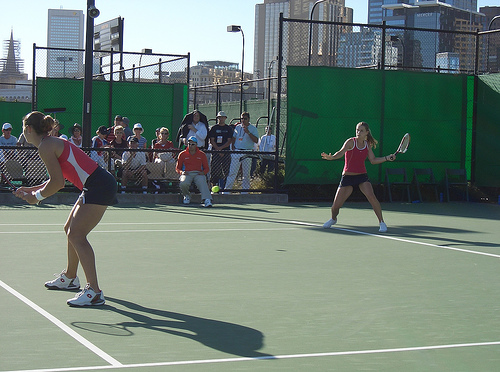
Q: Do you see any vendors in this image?
A: No, there are no vendors.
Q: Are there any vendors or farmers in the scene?
A: No, there are no vendors or farmers.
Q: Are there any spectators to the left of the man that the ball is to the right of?
A: Yes, there is a spectator to the left of the man.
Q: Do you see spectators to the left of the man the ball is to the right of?
A: Yes, there is a spectator to the left of the man.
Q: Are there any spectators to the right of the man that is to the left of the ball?
A: No, the spectator is to the left of the man.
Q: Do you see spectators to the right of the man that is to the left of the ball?
A: No, the spectator is to the left of the man.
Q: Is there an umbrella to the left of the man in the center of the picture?
A: No, there is a spectator to the left of the man.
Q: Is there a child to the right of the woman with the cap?
A: No, there is a spectator to the right of the woman.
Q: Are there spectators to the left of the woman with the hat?
A: Yes, there is a spectator to the left of the woman.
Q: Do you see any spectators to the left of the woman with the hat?
A: Yes, there is a spectator to the left of the woman.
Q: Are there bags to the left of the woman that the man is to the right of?
A: No, there is a spectator to the left of the woman.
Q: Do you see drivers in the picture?
A: No, there are no drivers.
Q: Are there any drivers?
A: No, there are no drivers.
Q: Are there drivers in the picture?
A: No, there are no drivers.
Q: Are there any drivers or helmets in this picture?
A: No, there are no drivers or helmets.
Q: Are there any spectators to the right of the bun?
A: Yes, there is a spectator to the right of the bun.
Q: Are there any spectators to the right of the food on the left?
A: Yes, there is a spectator to the right of the bun.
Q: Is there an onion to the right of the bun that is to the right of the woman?
A: No, there is a spectator to the right of the bun.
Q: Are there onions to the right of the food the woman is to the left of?
A: No, there is a spectator to the right of the bun.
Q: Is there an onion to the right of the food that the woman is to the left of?
A: No, there is a spectator to the right of the bun.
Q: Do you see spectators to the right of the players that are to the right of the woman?
A: Yes, there is a spectator to the right of the players.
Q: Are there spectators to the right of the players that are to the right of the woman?
A: Yes, there is a spectator to the right of the players.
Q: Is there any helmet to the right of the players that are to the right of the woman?
A: No, there is a spectator to the right of the players.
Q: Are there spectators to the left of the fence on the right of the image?
A: Yes, there is a spectator to the left of the fence.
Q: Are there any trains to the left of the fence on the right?
A: No, there is a spectator to the left of the fence.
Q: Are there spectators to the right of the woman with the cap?
A: Yes, there is a spectator to the right of the woman.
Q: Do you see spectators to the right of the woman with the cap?
A: Yes, there is a spectator to the right of the woman.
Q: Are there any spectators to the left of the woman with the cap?
A: No, the spectator is to the right of the woman.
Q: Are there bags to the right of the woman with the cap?
A: No, there is a spectator to the right of the woman.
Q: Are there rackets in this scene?
A: Yes, there is a racket.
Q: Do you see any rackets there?
A: Yes, there is a racket.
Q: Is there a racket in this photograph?
A: Yes, there is a racket.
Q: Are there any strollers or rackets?
A: Yes, there is a racket.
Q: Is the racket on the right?
A: Yes, the racket is on the right of the image.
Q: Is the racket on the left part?
A: No, the racket is on the right of the image.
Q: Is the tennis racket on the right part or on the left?
A: The tennis racket is on the right of the image.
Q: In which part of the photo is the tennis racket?
A: The tennis racket is on the right of the image.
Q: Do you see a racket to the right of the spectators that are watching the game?
A: Yes, there is a racket to the right of the spectators.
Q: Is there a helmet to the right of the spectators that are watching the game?
A: No, there is a racket to the right of the spectators.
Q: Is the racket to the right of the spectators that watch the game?
A: Yes, the racket is to the right of the spectators.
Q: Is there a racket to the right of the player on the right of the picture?
A: Yes, there is a racket to the right of the player.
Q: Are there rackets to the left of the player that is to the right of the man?
A: No, the racket is to the right of the player.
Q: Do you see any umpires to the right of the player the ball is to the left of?
A: No, there is a racket to the right of the player.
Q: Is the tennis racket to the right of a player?
A: Yes, the tennis racket is to the right of a player.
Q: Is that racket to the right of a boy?
A: No, the racket is to the right of a player.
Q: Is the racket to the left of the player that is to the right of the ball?
A: No, the racket is to the right of the player.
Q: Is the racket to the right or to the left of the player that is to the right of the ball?
A: The racket is to the right of the player.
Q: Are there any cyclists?
A: No, there are no cyclists.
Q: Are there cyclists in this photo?
A: No, there are no cyclists.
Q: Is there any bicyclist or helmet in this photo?
A: No, there are no cyclists or helmets.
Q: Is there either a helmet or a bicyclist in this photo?
A: No, there are no cyclists or helmets.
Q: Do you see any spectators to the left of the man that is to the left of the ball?
A: Yes, there is a spectator to the left of the man.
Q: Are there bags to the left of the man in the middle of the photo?
A: No, there is a spectator to the left of the man.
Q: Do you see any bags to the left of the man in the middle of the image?
A: No, there is a spectator to the left of the man.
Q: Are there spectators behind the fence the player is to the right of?
A: Yes, there is a spectator behind the fence.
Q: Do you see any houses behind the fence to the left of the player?
A: No, there is a spectator behind the fence.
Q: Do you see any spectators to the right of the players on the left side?
A: Yes, there is a spectator to the right of the players.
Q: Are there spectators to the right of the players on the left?
A: Yes, there is a spectator to the right of the players.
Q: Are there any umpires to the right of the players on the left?
A: No, there is a spectator to the right of the players.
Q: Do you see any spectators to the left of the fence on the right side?
A: Yes, there is a spectator to the left of the fence.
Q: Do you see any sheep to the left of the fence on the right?
A: No, there is a spectator to the left of the fence.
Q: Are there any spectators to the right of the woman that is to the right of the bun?
A: Yes, there is a spectator to the right of the woman.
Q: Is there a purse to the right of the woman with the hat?
A: No, there is a spectator to the right of the woman.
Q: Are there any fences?
A: Yes, there is a fence.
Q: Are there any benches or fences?
A: Yes, there is a fence.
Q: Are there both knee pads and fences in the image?
A: No, there is a fence but no knee pads.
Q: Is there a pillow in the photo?
A: No, there are no pillows.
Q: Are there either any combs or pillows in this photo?
A: No, there are no pillows or combs.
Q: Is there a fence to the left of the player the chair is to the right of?
A: Yes, there is a fence to the left of the player.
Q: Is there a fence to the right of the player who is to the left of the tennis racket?
A: No, the fence is to the left of the player.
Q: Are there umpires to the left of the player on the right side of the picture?
A: No, there is a fence to the left of the player.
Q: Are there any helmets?
A: No, there are no helmets.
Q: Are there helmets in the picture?
A: No, there are no helmets.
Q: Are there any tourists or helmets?
A: No, there are no helmets or tourists.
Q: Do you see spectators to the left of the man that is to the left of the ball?
A: Yes, there is a spectator to the left of the man.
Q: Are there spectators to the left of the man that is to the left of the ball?
A: Yes, there is a spectator to the left of the man.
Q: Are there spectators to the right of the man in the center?
A: No, the spectator is to the left of the man.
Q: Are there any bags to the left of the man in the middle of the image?
A: No, there is a spectator to the left of the man.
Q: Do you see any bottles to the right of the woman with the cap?
A: No, there is a spectator to the right of the woman.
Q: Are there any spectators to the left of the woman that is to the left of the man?
A: Yes, there is a spectator to the left of the woman.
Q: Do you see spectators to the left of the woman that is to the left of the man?
A: Yes, there is a spectator to the left of the woman.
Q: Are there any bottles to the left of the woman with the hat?
A: No, there is a spectator to the left of the woman.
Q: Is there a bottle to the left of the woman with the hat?
A: No, there is a spectator to the left of the woman.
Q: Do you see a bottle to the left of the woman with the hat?
A: No, there is a spectator to the left of the woman.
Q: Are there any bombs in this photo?
A: No, there are no bombs.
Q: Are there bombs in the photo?
A: No, there are no bombs.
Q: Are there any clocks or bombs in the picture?
A: No, there are no bombs or clocks.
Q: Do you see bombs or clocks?
A: No, there are no bombs or clocks.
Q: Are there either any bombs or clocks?
A: No, there are no bombs or clocks.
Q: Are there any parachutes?
A: No, there are no parachutes.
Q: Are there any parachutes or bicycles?
A: No, there are no parachutes or bicycles.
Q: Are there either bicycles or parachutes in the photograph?
A: No, there are no parachutes or bicycles.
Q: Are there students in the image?
A: No, there are no students.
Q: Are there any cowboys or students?
A: No, there are no students or cowboys.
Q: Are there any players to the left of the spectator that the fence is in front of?
A: Yes, there are players to the left of the spectator.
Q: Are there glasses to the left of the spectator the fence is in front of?
A: No, there are players to the left of the spectator.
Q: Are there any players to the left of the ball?
A: Yes, there are players to the left of the ball.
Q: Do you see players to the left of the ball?
A: Yes, there are players to the left of the ball.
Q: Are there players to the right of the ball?
A: No, the players are to the left of the ball.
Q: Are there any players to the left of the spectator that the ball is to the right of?
A: Yes, there are players to the left of the spectator.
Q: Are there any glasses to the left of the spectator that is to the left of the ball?
A: No, there are players to the left of the spectator.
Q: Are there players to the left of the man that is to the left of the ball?
A: Yes, there are players to the left of the man.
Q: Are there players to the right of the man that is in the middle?
A: No, the players are to the left of the man.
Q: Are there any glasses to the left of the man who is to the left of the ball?
A: No, there are players to the left of the man.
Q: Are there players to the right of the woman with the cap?
A: Yes, there are players to the right of the woman.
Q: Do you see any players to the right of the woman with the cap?
A: Yes, there are players to the right of the woman.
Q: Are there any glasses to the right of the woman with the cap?
A: No, there are players to the right of the woman.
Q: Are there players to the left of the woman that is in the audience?
A: Yes, there are players to the left of the woman.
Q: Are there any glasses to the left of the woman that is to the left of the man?
A: No, there are players to the left of the woman.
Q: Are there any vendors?
A: No, there are no vendors.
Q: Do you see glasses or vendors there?
A: No, there are no vendors or glasses.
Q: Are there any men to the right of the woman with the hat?
A: Yes, there is a man to the right of the woman.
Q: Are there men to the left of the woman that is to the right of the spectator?
A: No, the man is to the right of the woman.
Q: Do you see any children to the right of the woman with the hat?
A: No, there is a man to the right of the woman.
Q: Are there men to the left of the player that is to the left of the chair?
A: Yes, there is a man to the left of the player.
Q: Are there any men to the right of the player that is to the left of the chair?
A: No, the man is to the left of the player.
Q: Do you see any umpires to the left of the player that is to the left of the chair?
A: No, there is a man to the left of the player.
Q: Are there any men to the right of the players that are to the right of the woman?
A: Yes, there is a man to the right of the players.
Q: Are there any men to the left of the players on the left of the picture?
A: No, the man is to the right of the players.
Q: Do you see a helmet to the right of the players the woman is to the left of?
A: No, there is a man to the right of the players.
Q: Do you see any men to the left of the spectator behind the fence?
A: No, the man is to the right of the spectator.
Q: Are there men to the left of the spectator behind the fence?
A: No, the man is to the right of the spectator.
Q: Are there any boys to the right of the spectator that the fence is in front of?
A: No, there is a man to the right of the spectator.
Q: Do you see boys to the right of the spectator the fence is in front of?
A: No, there is a man to the right of the spectator.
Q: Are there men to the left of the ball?
A: Yes, there is a man to the left of the ball.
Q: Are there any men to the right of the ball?
A: No, the man is to the left of the ball.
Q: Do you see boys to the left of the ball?
A: No, there is a man to the left of the ball.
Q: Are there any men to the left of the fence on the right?
A: Yes, there is a man to the left of the fence.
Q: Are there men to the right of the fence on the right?
A: No, the man is to the left of the fence.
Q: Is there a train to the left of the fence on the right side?
A: No, there is a man to the left of the fence.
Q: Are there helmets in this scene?
A: No, there are no helmets.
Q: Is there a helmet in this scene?
A: No, there are no helmets.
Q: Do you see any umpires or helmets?
A: No, there are no helmets or umpires.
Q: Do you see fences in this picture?
A: Yes, there is a fence.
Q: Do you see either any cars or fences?
A: Yes, there is a fence.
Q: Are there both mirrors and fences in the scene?
A: No, there is a fence but no mirrors.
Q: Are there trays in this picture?
A: No, there are no trays.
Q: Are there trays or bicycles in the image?
A: No, there are no trays or bicycles.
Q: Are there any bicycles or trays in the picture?
A: No, there are no trays or bicycles.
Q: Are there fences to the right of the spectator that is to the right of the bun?
A: Yes, there is a fence to the right of the spectator.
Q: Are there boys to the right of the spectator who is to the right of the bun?
A: No, there is a fence to the right of the spectator.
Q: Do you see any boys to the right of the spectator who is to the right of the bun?
A: No, there is a fence to the right of the spectator.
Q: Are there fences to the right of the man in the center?
A: Yes, there is a fence to the right of the man.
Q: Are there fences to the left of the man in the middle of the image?
A: No, the fence is to the right of the man.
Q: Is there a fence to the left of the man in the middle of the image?
A: No, the fence is to the right of the man.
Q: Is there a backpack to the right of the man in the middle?
A: No, there is a fence to the right of the man.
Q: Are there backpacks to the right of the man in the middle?
A: No, there is a fence to the right of the man.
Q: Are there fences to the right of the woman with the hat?
A: Yes, there is a fence to the right of the woman.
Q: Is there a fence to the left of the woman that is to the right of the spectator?
A: No, the fence is to the right of the woman.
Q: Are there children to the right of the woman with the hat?
A: No, there is a fence to the right of the woman.